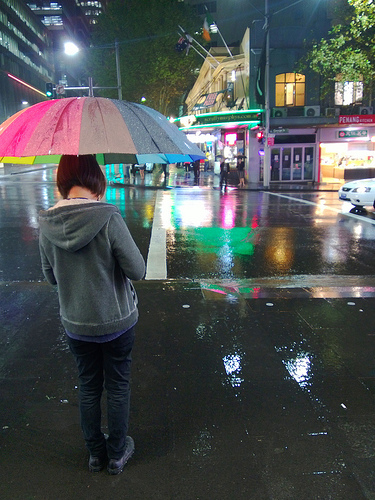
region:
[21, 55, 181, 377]
Woman is holding umbrella in hand.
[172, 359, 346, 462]
Road is grey color.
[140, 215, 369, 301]
White lines on road.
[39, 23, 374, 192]
Lights are on.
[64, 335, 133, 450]
Woman is wearing black pant.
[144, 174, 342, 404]
Light reflection is seen in road.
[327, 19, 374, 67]
Leaves are green color.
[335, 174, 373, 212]
White color car is parked.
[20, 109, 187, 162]
Umbrella is rainbow color.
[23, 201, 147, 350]
Woman is wearing grey shirt.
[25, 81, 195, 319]
girl holding an umbrella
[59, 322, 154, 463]
pants on the girl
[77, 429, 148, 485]
shoes on the girl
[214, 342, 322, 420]
wet sidewalk next to girl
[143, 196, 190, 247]
white line across the street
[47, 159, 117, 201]
short hair of the girl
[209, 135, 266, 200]
people across the street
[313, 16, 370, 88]
tree above the street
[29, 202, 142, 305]
jacket on girl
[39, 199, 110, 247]
hood of the jacket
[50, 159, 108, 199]
short hair on woman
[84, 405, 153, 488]
shows on the woman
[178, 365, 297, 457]
rain on the ground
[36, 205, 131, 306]
jacket on the girl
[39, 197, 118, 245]
hood on jacket of girl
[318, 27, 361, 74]
green leaves on tree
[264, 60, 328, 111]
window on a building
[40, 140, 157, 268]
girl with back towards camera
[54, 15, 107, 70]
white light above street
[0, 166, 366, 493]
the ground is wet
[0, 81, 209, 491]
the woman is holding an umbrella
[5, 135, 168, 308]
the woman is looking down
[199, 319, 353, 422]
a reflection of lights is on the ground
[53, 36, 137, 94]
the street light is on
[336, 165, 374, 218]
the car is stopped at street light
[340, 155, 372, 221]
the car is white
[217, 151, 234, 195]
the man is waiting to cross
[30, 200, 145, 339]
the woman's jacket is gray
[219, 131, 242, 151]
the light is red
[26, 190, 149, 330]
The gray sweater the girl is wearing.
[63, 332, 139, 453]
The black pants the girl is wearing.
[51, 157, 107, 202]
The girl's short brown hair.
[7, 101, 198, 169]
The colorful umbrella the girl is holding.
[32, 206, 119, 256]
The hood of the gray sweater the girl is wearing.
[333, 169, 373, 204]
The front of the white car in the street.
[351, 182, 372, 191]
The front light of the white car in the street.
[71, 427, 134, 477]
The sneakers the girl is wearing.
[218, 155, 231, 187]
The person in a black jacket and black pants standing across the street.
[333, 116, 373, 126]
The red business sign with the work Pemang written on it across the street.